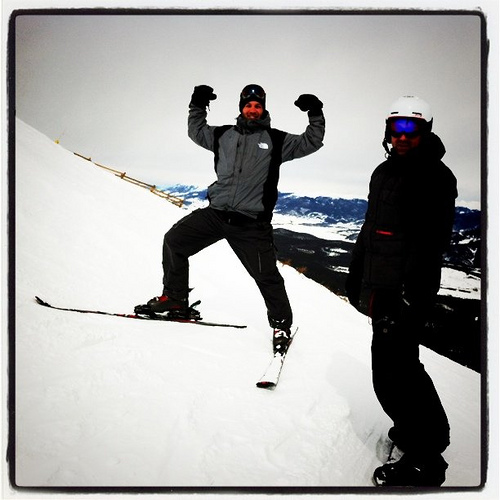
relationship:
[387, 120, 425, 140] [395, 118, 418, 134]
goggles are tinted blue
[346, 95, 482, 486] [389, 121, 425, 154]
man has face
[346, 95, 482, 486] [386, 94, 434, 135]
man wears helmet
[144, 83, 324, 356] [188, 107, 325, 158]
man showing muscles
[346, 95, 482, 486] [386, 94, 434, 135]
man wearing helmet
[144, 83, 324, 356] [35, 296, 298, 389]
man wearing skis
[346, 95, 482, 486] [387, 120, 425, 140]
man wearing goggles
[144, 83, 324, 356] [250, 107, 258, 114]
man has red nose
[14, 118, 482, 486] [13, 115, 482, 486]
mountains covered in snow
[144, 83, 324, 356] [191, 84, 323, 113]
man wearing gloves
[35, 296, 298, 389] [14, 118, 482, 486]
skis on top of mountains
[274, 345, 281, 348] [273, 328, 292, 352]
snow on top of man's foot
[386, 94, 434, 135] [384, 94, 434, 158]
helmet on top of head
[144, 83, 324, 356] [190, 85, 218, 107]
man has glove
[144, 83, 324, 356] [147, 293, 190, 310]
man has boot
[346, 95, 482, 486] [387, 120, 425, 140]
man has goggles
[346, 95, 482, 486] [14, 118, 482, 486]
man on mountain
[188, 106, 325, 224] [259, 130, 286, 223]
jacket has black line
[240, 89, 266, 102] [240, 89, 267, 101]
goggles on top of forehead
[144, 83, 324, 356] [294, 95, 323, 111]
man has left hand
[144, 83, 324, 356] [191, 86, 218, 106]
man has right hand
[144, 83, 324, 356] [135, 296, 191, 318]
man has right foot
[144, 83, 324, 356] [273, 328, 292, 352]
man has left foot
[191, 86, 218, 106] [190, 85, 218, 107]
right hand inside glove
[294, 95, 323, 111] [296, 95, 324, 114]
left hand inside glove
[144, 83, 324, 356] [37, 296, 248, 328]
man wearing ski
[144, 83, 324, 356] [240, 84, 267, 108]
man wearing black hat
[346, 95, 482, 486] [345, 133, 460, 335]
man has black jacket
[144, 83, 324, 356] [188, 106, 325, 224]
man wearing grey jacket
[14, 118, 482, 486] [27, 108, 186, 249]
people on a ski hill